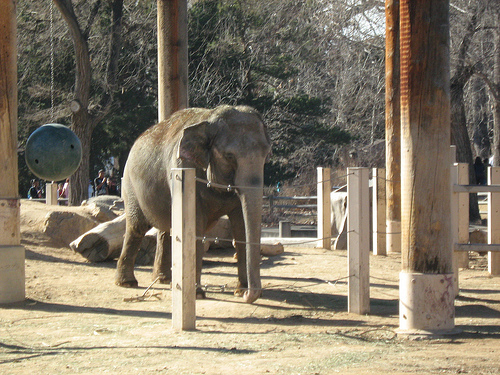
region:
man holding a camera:
[88, 159, 121, 202]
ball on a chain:
[29, 40, 80, 189]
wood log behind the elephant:
[53, 199, 120, 270]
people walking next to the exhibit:
[30, 177, 73, 201]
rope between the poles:
[219, 178, 338, 309]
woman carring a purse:
[60, 182, 69, 198]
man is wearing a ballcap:
[95, 165, 103, 176]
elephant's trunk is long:
[234, 280, 277, 303]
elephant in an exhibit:
[106, 72, 314, 343]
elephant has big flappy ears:
[165, 115, 223, 178]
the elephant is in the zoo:
[106, 110, 303, 336]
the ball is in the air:
[19, 120, 104, 195]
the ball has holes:
[25, 119, 98, 204]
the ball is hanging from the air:
[23, 115, 109, 182]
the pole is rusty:
[393, 24, 480, 143]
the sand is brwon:
[64, 303, 174, 373]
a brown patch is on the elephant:
[136, 95, 207, 144]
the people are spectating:
[38, 183, 120, 199]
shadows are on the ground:
[467, 277, 499, 351]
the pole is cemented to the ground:
[388, 6, 477, 329]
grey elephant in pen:
[114, 103, 313, 335]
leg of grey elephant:
[109, 254, 148, 292]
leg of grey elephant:
[151, 256, 174, 290]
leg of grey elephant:
[183, 268, 218, 310]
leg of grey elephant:
[229, 262, 249, 293]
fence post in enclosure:
[161, 236, 206, 338]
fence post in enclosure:
[341, 243, 381, 318]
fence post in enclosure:
[299, 180, 327, 243]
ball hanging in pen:
[23, 129, 100, 191]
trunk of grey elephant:
[244, 215, 268, 309]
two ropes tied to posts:
[209, 175, 325, 252]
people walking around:
[29, 177, 74, 202]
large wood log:
[74, 218, 112, 259]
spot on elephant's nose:
[238, 169, 263, 189]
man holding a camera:
[102, 165, 117, 184]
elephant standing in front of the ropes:
[165, 212, 262, 301]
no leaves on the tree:
[286, 41, 403, 142]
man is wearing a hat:
[94, 162, 109, 176]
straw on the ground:
[294, 325, 357, 340]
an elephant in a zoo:
[85, 90, 295, 317]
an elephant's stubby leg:
[105, 215, 150, 295]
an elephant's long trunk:
[230, 181, 270, 301]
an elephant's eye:
[225, 147, 232, 158]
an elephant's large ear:
[170, 122, 215, 172]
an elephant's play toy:
[17, 115, 87, 185]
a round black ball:
[16, 111, 86, 181]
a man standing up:
[87, 165, 115, 201]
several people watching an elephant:
[18, 168, 113, 204]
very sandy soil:
[17, 307, 172, 369]